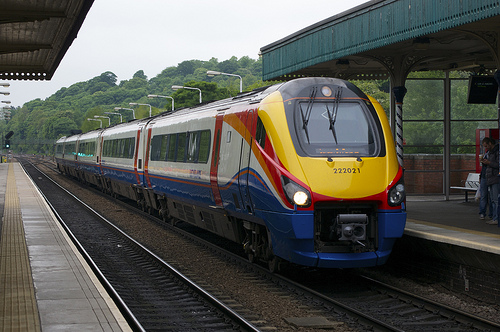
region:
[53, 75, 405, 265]
the train on the track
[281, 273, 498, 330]
the track in front of the train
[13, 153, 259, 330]
the track next to the train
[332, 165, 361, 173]
the numbers in front of the train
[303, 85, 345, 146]
the windshield wipers on the windshield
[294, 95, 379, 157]
the windshield on the train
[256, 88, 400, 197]
the yellow paint on the front of the train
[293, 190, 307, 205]
the headlight at the front of the train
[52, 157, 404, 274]
the blue paint on the train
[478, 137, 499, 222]
the people standing near the train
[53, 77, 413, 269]
Red, blue and yellow high speed public train.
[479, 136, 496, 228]
Man standing and texting on a train platform.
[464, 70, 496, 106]
A black sign giving passengers directions.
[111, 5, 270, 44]
Cloudness clear but grayish sky.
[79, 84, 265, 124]
Row of overhead lights at train station.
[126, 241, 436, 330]
Black train tracks with a train on one side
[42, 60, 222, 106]
Tall trees with green tops in the background.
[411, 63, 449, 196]
Protective glass encasing train passengers at train stop.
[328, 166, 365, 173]
The train's number is 222021and it's posted on the front.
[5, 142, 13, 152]
Green go ahead train light on the left side of train station.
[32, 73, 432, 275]
train on the tracks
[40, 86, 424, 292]
yellow, red, blue, and white train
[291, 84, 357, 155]
windshield wipers on the front of the train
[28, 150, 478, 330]
two parallel sets of train tracks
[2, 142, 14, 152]
green light shining in the distance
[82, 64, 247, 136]
row of light poles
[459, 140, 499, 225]
people standing near the tracks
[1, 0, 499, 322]
train in the station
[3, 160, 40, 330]
thick yellow line on the ground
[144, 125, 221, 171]
row of windows on the train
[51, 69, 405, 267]
a white, red, blue, and orange passenger train at a station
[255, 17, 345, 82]
the top of a train station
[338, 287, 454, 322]
part of railway tracks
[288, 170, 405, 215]
train headlights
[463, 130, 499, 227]
two people waiting for a train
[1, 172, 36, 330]
train station platform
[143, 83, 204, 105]
two train station lights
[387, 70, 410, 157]
striped pole at a train station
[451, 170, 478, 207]
part of a bench at a train station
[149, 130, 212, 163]
glass train windows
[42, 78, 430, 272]
A train on a track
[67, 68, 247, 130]
Streetlights above the train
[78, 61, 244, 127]
Streetlights in a row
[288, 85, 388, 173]
the windshield on a train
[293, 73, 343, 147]
wiperson on a train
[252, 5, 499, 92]
The roof at a train depot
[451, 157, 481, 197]
a bench at a train depot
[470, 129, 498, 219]
a person waiting for a train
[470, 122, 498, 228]
a person in a train depot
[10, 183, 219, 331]
An empty train track